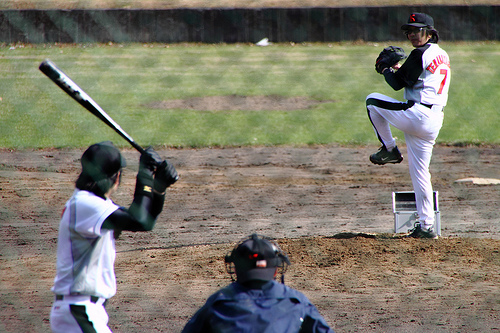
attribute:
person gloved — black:
[30, 54, 180, 331]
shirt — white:
[50, 184, 137, 297]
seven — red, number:
[438, 68, 448, 95]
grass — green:
[0, 40, 499, 142]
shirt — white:
[416, 44, 482, 103]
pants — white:
[365, 91, 443, 233]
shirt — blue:
[176, 279, 329, 330]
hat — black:
[400, 7, 447, 36]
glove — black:
[364, 40, 412, 82]